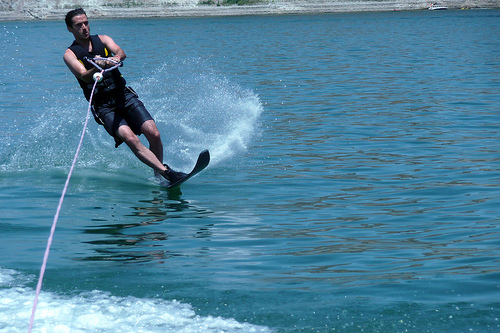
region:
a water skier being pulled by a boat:
[16, 4, 216, 329]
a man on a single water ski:
[50, 6, 235, 233]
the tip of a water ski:
[169, 149, 221, 191]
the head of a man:
[58, 5, 93, 45]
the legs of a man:
[97, 104, 180, 190]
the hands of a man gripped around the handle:
[86, 52, 122, 74]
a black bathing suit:
[88, 95, 156, 148]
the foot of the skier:
[161, 159, 189, 186]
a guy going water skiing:
[45, 15, 273, 220]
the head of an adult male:
[64, 6, 101, 41]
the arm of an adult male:
[52, 39, 86, 81]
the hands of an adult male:
[97, 55, 114, 65]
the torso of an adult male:
[78, 45, 116, 93]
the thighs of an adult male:
[98, 112, 159, 127]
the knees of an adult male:
[121, 122, 165, 143]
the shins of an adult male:
[118, 141, 173, 173]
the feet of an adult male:
[152, 149, 197, 199]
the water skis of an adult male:
[168, 153, 219, 207]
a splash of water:
[170, 73, 257, 143]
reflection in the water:
[86, 208, 170, 273]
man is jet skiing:
[61, 8, 178, 172]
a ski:
[192, 146, 211, 176]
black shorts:
[106, 105, 147, 125]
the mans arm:
[115, 45, 123, 60]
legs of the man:
[120, 130, 175, 175]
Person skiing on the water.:
[56, 8, 213, 190]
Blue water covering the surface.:
[1, 11, 496, 331]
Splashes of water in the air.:
[14, 56, 266, 188]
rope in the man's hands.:
[23, 48, 113, 331]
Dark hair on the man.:
[59, 7, 96, 43]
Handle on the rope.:
[79, 48, 124, 72]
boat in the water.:
[422, 2, 449, 14]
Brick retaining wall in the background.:
[0, 0, 497, 20]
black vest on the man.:
[55, 10, 135, 99]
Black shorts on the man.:
[58, 9, 161, 147]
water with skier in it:
[6, 25, 476, 292]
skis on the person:
[148, 153, 240, 184]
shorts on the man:
[94, 86, 149, 131]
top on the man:
[72, 41, 127, 84]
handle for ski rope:
[78, 53, 125, 78]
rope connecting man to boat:
[15, 84, 95, 331]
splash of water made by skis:
[148, 84, 260, 152]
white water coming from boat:
[18, 286, 145, 328]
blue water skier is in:
[287, 100, 459, 252]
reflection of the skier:
[83, 200, 210, 277]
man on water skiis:
[62, 5, 210, 179]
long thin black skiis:
[166, 147, 213, 185]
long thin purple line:
[24, 55, 126, 332]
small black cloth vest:
[68, 31, 128, 99]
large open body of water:
[0, 10, 497, 332]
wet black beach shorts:
[94, 86, 156, 148]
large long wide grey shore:
[0, 0, 496, 16]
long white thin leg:
[114, 124, 169, 173]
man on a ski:
[62, 10, 209, 182]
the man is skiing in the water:
[55, 8, 253, 188]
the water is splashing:
[138, 62, 260, 159]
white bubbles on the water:
[4, 273, 244, 332]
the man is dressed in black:
[62, 6, 152, 139]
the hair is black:
[64, 7, 86, 22]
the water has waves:
[300, 128, 429, 225]